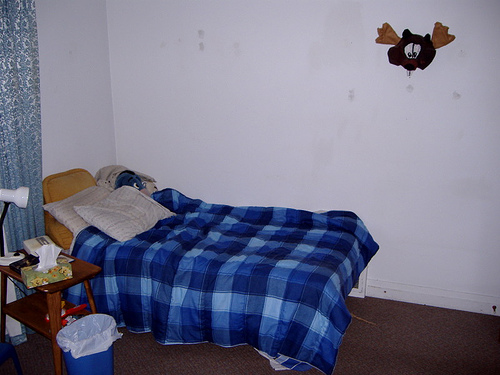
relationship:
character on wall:
[371, 13, 456, 77] [105, 0, 498, 312]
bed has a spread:
[40, 163, 385, 374] [62, 185, 391, 374]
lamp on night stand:
[0, 186, 30, 266] [0, 240, 109, 373]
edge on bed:
[78, 233, 332, 300] [40, 163, 385, 374]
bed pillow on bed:
[72, 184, 177, 243] [32, 163, 369, 360]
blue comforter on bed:
[55, 187, 382, 374] [40, 163, 385, 374]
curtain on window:
[3, 0, 51, 261] [3, 1, 48, 271]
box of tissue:
[15, 255, 76, 291] [32, 241, 63, 273]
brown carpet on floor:
[8, 292, 495, 373] [3, 280, 497, 373]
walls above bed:
[31, 3, 497, 307] [35, 147, 357, 374]